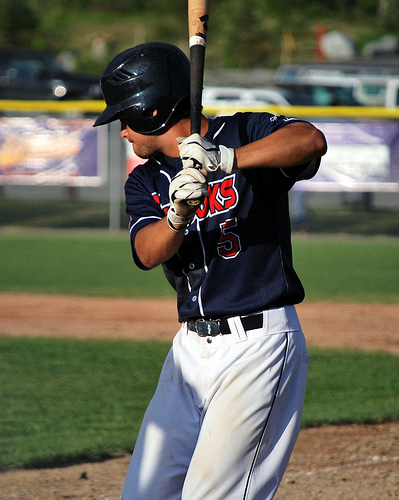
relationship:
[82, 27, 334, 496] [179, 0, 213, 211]
batter holding bat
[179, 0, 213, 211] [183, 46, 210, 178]
bat has handle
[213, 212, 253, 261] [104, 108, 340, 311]
number on shirt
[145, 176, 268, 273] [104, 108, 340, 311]
lettering on shirt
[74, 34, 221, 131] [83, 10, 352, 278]
helmet for batting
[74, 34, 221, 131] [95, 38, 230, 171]
helmet on head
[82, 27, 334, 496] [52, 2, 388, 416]
guy playing baseball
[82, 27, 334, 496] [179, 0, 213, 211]
player holding bat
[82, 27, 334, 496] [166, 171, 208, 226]
player wearing glove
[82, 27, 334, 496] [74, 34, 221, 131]
player wearing helmet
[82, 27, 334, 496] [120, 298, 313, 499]
player wearing trousers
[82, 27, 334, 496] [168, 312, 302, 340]
batter wearing belt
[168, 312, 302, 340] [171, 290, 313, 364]
belt on waist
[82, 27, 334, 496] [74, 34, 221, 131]
batter wears helmet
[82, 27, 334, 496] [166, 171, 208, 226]
batter wearing glove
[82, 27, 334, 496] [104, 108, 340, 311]
batter wearing jersey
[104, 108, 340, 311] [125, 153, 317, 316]
jersey has trim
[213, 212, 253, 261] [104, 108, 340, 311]
number on jersey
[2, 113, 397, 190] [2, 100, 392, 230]
advertising on wall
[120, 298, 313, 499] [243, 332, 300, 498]
pants have trim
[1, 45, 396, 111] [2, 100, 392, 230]
cars behind wall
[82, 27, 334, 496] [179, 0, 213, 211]
man holding bat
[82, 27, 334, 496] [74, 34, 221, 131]
man wearing helmet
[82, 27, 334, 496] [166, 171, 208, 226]
man wearing glove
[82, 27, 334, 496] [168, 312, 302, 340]
man wearing belt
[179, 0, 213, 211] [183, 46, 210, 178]
bat has dark coloring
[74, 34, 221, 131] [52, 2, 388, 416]
helmet for baseball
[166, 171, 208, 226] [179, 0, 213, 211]
glove holding bat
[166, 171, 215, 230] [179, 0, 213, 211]
glove holding bat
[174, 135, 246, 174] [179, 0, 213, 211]
glove holding bat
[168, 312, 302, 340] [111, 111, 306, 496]
belt on uniform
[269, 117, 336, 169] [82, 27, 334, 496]
elbow on man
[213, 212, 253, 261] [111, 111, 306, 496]
number on uniform